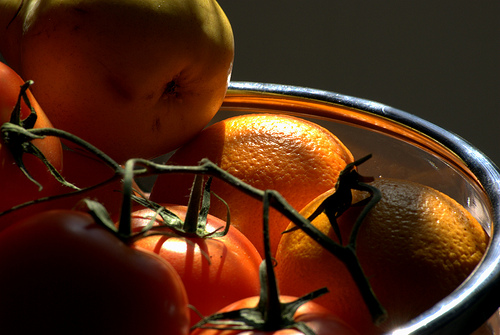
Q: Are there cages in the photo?
A: No, there are no cages.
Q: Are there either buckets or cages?
A: No, there are no cages or buckets.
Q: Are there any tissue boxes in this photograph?
A: No, there are no tissue boxes.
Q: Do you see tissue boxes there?
A: No, there are no tissue boxes.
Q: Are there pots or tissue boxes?
A: No, there are no tissue boxes or pots.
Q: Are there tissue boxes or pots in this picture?
A: No, there are no tissue boxes or pots.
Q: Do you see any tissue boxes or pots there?
A: No, there are no tissue boxes or pots.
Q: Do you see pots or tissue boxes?
A: No, there are no tissue boxes or pots.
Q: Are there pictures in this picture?
A: No, there are no pictures.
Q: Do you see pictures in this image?
A: No, there are no pictures.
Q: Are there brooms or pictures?
A: No, there are no pictures or brooms.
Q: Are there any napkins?
A: No, there are no napkins.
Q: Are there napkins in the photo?
A: No, there are no napkins.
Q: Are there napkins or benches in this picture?
A: No, there are no napkins or benches.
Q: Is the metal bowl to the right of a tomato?
A: Yes, the bowl is to the right of a tomato.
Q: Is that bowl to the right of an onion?
A: No, the bowl is to the right of a tomato.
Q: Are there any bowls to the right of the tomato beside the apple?
A: Yes, there is a bowl to the right of the tomato.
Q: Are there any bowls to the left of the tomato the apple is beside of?
A: No, the bowl is to the right of the tomato.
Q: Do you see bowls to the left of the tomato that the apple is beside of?
A: No, the bowl is to the right of the tomato.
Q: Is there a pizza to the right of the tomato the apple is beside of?
A: No, there is a bowl to the right of the tomato.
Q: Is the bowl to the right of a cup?
A: No, the bowl is to the right of a tomato.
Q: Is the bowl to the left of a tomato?
A: No, the bowl is to the right of a tomato.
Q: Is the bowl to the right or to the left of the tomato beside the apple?
A: The bowl is to the right of the tomato.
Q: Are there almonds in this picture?
A: No, there are no almonds.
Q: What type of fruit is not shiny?
A: The fruit is an apple.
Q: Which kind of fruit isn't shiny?
A: The fruit is an apple.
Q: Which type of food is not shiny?
A: The food is an apple.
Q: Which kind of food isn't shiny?
A: The food is an apple.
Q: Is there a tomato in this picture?
A: Yes, there is a tomato.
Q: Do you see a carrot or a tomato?
A: Yes, there is a tomato.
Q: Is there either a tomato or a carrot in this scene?
A: Yes, there is a tomato.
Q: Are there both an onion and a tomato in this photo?
A: No, there is a tomato but no onions.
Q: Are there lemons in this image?
A: No, there are no lemons.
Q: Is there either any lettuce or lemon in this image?
A: No, there are no lemons or lettuce.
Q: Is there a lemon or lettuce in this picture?
A: No, there are no lemons or lettuce.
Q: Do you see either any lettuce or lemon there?
A: No, there are no lemons or lettuce.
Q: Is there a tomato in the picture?
A: Yes, there is a tomato.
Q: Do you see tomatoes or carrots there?
A: Yes, there is a tomato.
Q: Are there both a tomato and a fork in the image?
A: No, there is a tomato but no forks.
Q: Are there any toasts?
A: No, there are no toasts.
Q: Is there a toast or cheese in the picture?
A: No, there are no toasts or cheese.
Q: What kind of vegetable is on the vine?
A: The vegetable is a tomato.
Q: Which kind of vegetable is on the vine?
A: The vegetable is a tomato.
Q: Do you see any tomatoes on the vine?
A: Yes, there is a tomato on the vine.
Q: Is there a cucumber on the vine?
A: No, there is a tomato on the vine.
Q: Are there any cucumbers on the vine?
A: No, there is a tomato on the vine.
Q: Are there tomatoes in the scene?
A: Yes, there is a tomato.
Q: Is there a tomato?
A: Yes, there is a tomato.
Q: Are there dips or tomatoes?
A: Yes, there is a tomato.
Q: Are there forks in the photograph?
A: No, there are no forks.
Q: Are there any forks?
A: No, there are no forks.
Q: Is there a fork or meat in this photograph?
A: No, there are no forks or meat.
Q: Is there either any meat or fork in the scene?
A: No, there are no forks or meat.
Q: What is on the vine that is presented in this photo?
A: The tomato is on the vine.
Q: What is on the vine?
A: The tomato is on the vine.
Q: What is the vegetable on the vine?
A: The vegetable is a tomato.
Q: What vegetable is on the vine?
A: The vegetable is a tomato.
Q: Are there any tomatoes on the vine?
A: Yes, there is a tomato on the vine.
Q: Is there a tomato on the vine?
A: Yes, there is a tomato on the vine.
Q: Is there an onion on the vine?
A: No, there is a tomato on the vine.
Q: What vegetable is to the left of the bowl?
A: The vegetable is a tomato.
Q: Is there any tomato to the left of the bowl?
A: Yes, there is a tomato to the left of the bowl.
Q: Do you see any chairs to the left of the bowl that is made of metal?
A: No, there is a tomato to the left of the bowl.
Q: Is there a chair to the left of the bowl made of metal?
A: No, there is a tomato to the left of the bowl.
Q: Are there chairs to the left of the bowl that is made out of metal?
A: No, there is a tomato to the left of the bowl.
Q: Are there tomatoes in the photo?
A: Yes, there is a tomato.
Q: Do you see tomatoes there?
A: Yes, there is a tomato.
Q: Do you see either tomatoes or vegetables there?
A: Yes, there is a tomato.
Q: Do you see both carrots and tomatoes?
A: No, there is a tomato but no carrots.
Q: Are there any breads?
A: No, there are no breads.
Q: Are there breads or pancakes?
A: No, there are no breads or pancakes.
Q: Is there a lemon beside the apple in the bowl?
A: No, there is a tomato beside the apple.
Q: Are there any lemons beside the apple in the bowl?
A: No, there is a tomato beside the apple.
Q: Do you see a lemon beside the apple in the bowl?
A: No, there is a tomato beside the apple.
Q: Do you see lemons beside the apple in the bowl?
A: No, there is a tomato beside the apple.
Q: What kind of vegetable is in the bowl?
A: The vegetable is a tomato.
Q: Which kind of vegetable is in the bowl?
A: The vegetable is a tomato.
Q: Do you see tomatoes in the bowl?
A: Yes, there is a tomato in the bowl.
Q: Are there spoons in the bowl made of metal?
A: No, there is a tomato in the bowl.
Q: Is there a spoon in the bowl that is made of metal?
A: No, there is a tomato in the bowl.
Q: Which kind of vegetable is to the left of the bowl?
A: The vegetable is a tomato.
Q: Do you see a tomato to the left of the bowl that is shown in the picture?
A: Yes, there is a tomato to the left of the bowl.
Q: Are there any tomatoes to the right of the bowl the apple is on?
A: No, the tomato is to the left of the bowl.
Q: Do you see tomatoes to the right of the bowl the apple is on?
A: No, the tomato is to the left of the bowl.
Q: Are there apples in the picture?
A: Yes, there is an apple.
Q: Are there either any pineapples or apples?
A: Yes, there is an apple.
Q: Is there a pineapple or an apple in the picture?
A: Yes, there is an apple.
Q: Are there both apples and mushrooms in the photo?
A: No, there is an apple but no mushrooms.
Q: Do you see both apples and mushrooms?
A: No, there is an apple but no mushrooms.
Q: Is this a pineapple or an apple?
A: This is an apple.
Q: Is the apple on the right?
A: No, the apple is on the left of the image.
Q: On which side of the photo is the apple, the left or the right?
A: The apple is on the left of the image.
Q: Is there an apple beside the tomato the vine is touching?
A: Yes, there is an apple beside the tomato.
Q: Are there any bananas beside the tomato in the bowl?
A: No, there is an apple beside the tomato.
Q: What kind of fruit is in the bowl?
A: The fruit is an apple.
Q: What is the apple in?
A: The apple is in the bowl.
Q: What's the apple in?
A: The apple is in the bowl.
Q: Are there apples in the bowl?
A: Yes, there is an apple in the bowl.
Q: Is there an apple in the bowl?
A: Yes, there is an apple in the bowl.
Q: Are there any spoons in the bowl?
A: No, there is an apple in the bowl.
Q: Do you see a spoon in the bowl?
A: No, there is an apple in the bowl.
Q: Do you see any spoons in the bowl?
A: No, there is an apple in the bowl.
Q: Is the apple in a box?
A: No, the apple is in the bowl.